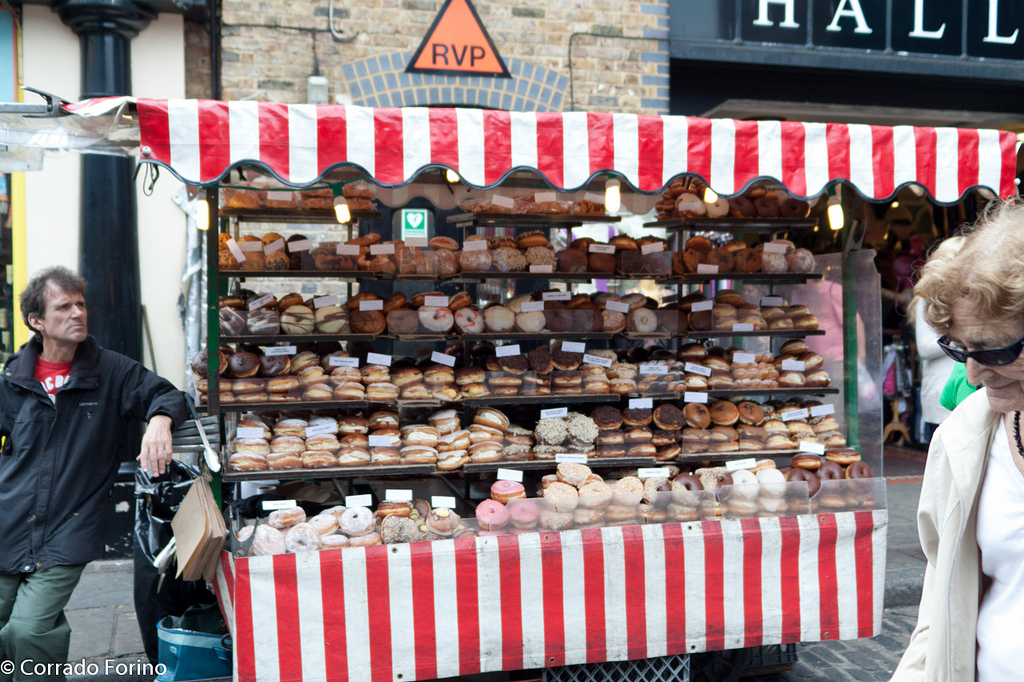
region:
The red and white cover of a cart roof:
[461, 113, 598, 164]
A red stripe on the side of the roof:
[384, 113, 401, 175]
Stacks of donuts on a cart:
[220, 362, 429, 394]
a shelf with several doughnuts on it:
[228, 417, 854, 466]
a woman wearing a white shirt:
[980, 418, 1020, 638]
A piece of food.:
[471, 491, 507, 531]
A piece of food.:
[547, 473, 586, 505]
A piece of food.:
[553, 456, 577, 469]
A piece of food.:
[568, 415, 588, 439]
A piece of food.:
[599, 405, 615, 424]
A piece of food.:
[620, 403, 644, 419]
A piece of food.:
[654, 399, 673, 418]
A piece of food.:
[705, 399, 738, 419]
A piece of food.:
[635, 308, 661, 343]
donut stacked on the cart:
[456, 488, 511, 527]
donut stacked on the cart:
[487, 473, 522, 500]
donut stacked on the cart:
[558, 457, 585, 477]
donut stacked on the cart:
[592, 400, 621, 427]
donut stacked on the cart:
[618, 397, 654, 426]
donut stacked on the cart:
[655, 396, 681, 429]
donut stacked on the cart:
[675, 390, 708, 422]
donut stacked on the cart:
[538, 479, 574, 505]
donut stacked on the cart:
[337, 502, 377, 535]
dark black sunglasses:
[933, 323, 1019, 365]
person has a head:
[16, 267, 89, 345]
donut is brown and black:
[593, 406, 625, 430]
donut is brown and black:
[650, 404, 686, 433]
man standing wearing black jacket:
[6, 268, 184, 680]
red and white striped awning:
[49, 91, 1023, 209]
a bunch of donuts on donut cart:
[209, 211, 871, 531]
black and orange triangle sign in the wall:
[404, 0, 510, 77]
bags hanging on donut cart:
[168, 477, 232, 582]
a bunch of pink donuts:
[470, 478, 540, 529]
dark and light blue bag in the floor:
[155, 612, 233, 680]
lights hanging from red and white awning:
[185, 177, 853, 232]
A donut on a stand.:
[468, 495, 503, 530]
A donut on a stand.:
[499, 479, 528, 500]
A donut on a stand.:
[505, 491, 534, 518]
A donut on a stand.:
[543, 476, 582, 511]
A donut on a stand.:
[581, 478, 611, 507]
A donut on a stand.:
[566, 459, 596, 492]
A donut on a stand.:
[634, 472, 667, 498]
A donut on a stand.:
[669, 476, 688, 497]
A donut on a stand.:
[699, 471, 735, 503]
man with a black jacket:
[0, 253, 206, 672]